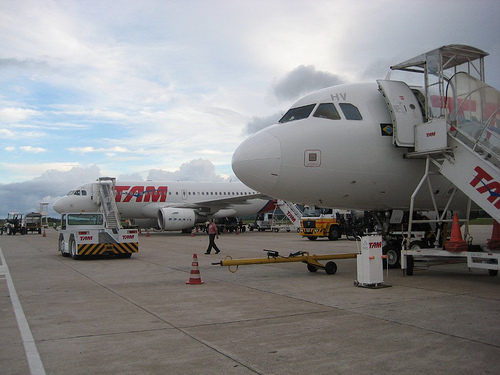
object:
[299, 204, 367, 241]
truck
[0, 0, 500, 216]
cloud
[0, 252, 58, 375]
lines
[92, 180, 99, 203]
open door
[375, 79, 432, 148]
open door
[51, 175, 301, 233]
airplane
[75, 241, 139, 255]
stripes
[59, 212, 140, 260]
back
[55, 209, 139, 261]
truck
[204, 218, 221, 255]
man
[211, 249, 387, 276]
equipment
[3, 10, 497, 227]
sky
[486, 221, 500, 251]
cone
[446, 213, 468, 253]
cone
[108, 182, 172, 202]
two zebras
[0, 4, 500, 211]
sky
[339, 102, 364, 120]
window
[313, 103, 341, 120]
window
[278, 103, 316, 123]
window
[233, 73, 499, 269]
airplane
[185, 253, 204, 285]
cone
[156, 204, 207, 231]
engine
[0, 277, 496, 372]
pavement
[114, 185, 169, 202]
text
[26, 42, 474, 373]
airport